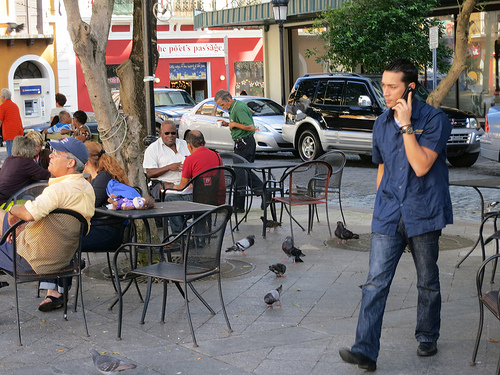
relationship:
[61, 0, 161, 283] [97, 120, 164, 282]
tree has trunk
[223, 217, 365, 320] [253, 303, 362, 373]
pigeons are on ground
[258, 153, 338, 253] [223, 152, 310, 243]
chair at table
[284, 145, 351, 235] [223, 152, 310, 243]
chair at table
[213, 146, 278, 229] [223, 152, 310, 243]
chair at table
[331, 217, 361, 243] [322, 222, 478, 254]
pigeon stands on manhole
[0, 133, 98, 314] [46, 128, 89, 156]
he wears cap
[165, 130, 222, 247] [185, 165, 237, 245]
man sits on chair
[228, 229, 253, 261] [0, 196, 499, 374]
bird walking on ground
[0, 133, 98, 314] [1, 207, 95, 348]
he in chair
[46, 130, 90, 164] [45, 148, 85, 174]
cap on head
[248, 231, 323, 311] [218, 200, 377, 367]
pigeons on sidewalk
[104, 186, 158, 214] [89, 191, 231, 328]
doll on table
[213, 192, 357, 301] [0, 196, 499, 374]
pigeons on ground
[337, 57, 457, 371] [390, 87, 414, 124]
he walking and talking on phone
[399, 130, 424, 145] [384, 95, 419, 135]
watch on wrist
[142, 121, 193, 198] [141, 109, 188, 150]
man wearing sunglasses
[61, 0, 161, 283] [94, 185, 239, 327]
tree between tables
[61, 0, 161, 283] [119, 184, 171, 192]
tree between table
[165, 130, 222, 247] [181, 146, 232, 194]
man in shirt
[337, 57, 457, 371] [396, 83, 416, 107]
he talking on phone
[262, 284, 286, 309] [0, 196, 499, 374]
bird walking on ground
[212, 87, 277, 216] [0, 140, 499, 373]
man walking and looking at on ground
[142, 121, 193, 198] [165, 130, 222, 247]
man talking to man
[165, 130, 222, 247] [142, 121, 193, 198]
man talking to man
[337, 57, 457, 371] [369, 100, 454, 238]
he wears a navy shirt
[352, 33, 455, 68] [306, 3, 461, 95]
branches of tree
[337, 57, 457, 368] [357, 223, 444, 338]
he he wearing jeans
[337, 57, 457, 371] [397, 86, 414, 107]
he on phone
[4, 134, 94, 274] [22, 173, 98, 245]
he wearing a yellow shirt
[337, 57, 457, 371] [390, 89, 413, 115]
he holding phone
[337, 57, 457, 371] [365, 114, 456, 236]
he wearing a navy shirt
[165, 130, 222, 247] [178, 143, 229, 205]
man has on a shirt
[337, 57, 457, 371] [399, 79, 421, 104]
he holding a cellphone with hand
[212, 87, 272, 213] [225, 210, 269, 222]
man walking on sidewalk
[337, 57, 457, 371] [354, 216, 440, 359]
he wearing jeans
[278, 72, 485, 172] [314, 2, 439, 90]
car by tree